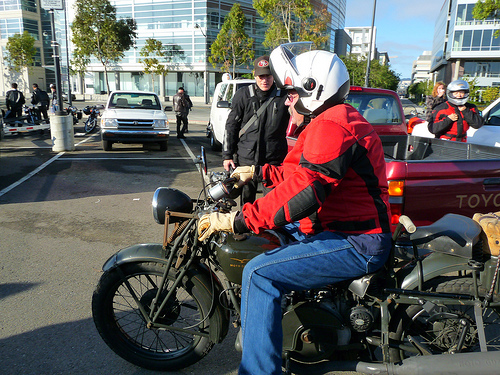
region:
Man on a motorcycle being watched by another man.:
[115, 25, 499, 358]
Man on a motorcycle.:
[209, 46, 404, 361]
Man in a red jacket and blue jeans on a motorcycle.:
[200, 15, 383, 373]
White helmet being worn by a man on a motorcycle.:
[256, 15, 366, 151]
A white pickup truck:
[100, 67, 175, 181]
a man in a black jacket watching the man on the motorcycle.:
[189, 33, 321, 238]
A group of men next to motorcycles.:
[4, 57, 96, 162]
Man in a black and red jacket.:
[385, 50, 496, 162]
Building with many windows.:
[46, 0, 276, 107]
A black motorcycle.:
[82, 168, 486, 368]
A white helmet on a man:
[267, 39, 351, 117]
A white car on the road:
[100, 83, 171, 153]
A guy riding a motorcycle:
[197, 45, 409, 366]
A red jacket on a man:
[232, 100, 406, 237]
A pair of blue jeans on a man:
[237, 236, 362, 371]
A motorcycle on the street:
[85, 140, 499, 370]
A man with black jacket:
[220, 47, 290, 209]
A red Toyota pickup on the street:
[347, 83, 497, 218]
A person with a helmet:
[428, 72, 484, 152]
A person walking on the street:
[171, 85, 193, 141]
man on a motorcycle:
[204, 41, 399, 368]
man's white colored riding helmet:
[264, 45, 355, 115]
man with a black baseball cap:
[224, 53, 288, 175]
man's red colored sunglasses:
[283, 92, 298, 104]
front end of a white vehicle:
[99, 85, 170, 151]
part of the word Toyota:
[453, 185, 498, 211]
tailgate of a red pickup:
[403, 158, 499, 228]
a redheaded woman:
[430, 78, 446, 109]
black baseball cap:
[252, 55, 274, 79]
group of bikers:
[4, 80, 61, 122]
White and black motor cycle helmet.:
[231, 29, 384, 118]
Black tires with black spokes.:
[96, 250, 220, 374]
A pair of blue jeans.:
[227, 220, 392, 374]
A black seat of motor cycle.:
[403, 196, 493, 280]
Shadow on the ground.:
[1, 295, 87, 371]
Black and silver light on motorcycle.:
[124, 174, 189, 248]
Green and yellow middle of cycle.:
[200, 228, 282, 304]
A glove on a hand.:
[170, 207, 253, 265]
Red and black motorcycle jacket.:
[248, 107, 395, 243]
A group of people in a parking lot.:
[16, 16, 451, 351]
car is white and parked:
[92, 82, 184, 160]